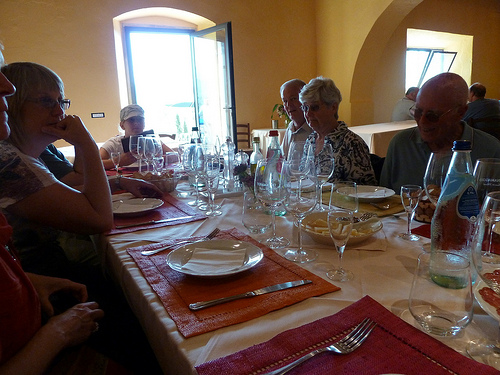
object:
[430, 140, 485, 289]
bottle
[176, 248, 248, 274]
napkin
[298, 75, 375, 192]
lady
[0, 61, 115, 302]
lady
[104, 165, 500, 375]
table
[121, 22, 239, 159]
door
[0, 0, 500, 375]
room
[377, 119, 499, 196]
blue shirt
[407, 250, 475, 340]
glass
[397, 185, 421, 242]
glass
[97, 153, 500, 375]
tablecloth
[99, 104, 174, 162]
boy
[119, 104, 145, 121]
hat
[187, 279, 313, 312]
utensil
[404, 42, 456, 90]
window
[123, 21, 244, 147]
window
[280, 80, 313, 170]
person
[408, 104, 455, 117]
glasses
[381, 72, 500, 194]
man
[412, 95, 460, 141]
face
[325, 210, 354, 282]
glass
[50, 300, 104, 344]
hand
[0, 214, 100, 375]
someone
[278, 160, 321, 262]
glass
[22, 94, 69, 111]
glasses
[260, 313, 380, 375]
fork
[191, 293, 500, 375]
cloth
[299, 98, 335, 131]
face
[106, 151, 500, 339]
mat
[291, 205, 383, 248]
bowl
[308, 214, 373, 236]
pasta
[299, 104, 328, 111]
glasses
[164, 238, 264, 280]
plate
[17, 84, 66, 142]
face